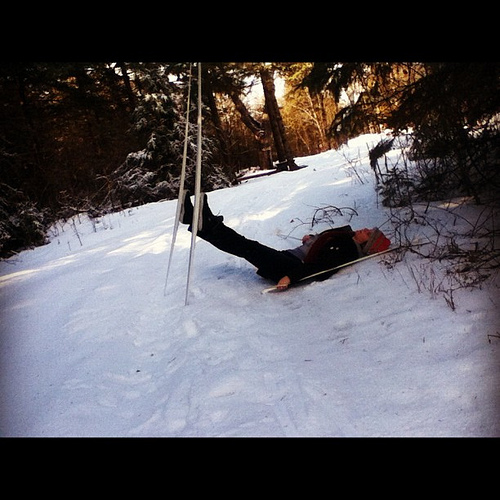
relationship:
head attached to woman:
[353, 227, 389, 257] [188, 207, 387, 265]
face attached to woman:
[355, 228, 375, 242] [188, 207, 387, 265]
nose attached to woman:
[363, 225, 369, 230] [188, 207, 387, 265]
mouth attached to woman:
[357, 231, 362, 235] [188, 207, 387, 265]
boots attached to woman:
[180, 191, 223, 231] [188, 207, 387, 265]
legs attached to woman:
[199, 229, 243, 265] [188, 207, 387, 265]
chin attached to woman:
[351, 231, 356, 235] [188, 207, 387, 265]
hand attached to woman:
[278, 278, 293, 288] [188, 207, 387, 265]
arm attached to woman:
[305, 254, 339, 274] [188, 207, 387, 265]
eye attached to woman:
[363, 227, 373, 238] [188, 207, 387, 265]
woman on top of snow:
[188, 207, 387, 265] [110, 306, 171, 342]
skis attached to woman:
[163, 92, 208, 303] [188, 207, 387, 265]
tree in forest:
[27, 71, 109, 222] [207, 60, 387, 180]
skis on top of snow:
[163, 92, 208, 303] [110, 306, 171, 342]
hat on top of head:
[371, 238, 398, 259] [353, 227, 389, 257]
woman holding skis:
[188, 207, 387, 265] [163, 92, 208, 303]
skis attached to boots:
[163, 92, 208, 303] [180, 191, 223, 231]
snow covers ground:
[110, 306, 171, 342] [251, 336, 367, 389]